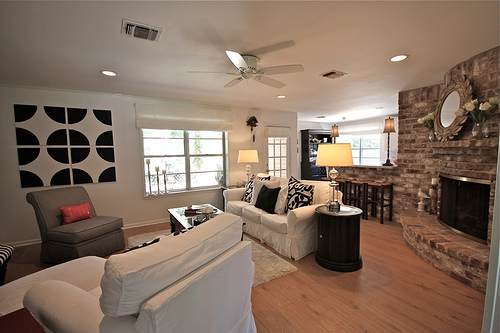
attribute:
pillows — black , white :
[243, 173, 315, 221]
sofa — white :
[227, 161, 357, 265]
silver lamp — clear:
[234, 145, 264, 180]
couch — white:
[220, 172, 346, 264]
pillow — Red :
[44, 177, 107, 229]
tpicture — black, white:
[14, 100, 117, 183]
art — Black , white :
[8, 97, 213, 237]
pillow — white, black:
[284, 171, 314, 218]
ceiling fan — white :
[188, 47, 306, 93]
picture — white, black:
[12, 100, 122, 189]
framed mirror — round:
[413, 79, 486, 143]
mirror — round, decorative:
[432, 71, 479, 141]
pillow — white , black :
[240, 172, 315, 214]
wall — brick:
[389, 43, 481, 290]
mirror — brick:
[432, 76, 471, 142]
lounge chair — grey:
[23, 183, 126, 262]